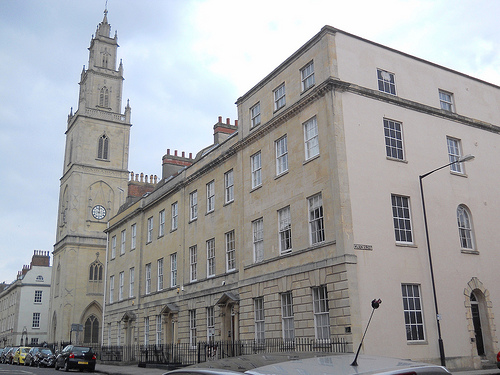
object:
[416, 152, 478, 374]
street light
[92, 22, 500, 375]
building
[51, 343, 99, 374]
vehicle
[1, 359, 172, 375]
street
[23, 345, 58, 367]
vehicle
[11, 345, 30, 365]
vehicle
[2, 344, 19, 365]
vehicle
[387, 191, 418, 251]
window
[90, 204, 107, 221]
clock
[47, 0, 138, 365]
tower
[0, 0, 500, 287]
sky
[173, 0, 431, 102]
cloud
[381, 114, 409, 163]
window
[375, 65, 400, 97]
window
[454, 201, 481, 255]
window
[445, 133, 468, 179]
window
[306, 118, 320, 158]
curtains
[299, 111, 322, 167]
window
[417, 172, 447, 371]
post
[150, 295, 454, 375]
car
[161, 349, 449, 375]
roof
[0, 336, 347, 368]
fence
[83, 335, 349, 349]
top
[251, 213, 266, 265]
window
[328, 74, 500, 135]
edge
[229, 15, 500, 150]
top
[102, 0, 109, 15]
cross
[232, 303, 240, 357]
pillar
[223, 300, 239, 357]
doorway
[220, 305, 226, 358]
pillar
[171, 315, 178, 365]
pillar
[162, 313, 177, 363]
doorway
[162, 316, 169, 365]
pillar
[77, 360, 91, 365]
license plate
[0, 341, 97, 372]
row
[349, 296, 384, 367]
antenna